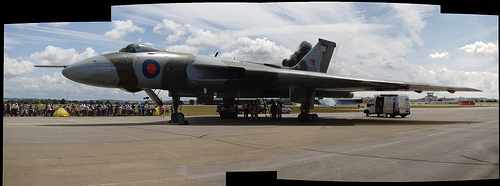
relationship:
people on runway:
[8, 97, 174, 117] [23, 121, 496, 166]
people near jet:
[8, 97, 174, 117] [46, 40, 477, 133]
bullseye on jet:
[137, 60, 163, 79] [46, 40, 477, 133]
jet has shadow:
[46, 40, 477, 133] [43, 119, 479, 131]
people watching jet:
[8, 97, 174, 117] [46, 40, 477, 133]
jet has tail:
[46, 40, 477, 133] [278, 34, 352, 91]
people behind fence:
[8, 97, 174, 117] [14, 116, 178, 119]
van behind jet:
[366, 93, 414, 118] [46, 40, 477, 133]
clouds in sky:
[144, 8, 282, 57] [142, 11, 485, 43]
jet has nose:
[46, 40, 477, 133] [64, 37, 104, 93]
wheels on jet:
[164, 114, 323, 132] [46, 40, 477, 133]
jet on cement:
[46, 40, 477, 133] [109, 126, 353, 169]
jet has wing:
[46, 40, 477, 133] [248, 37, 495, 109]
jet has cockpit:
[46, 40, 477, 133] [119, 45, 168, 68]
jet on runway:
[46, 40, 477, 133] [23, 121, 496, 166]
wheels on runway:
[164, 114, 323, 132] [23, 121, 496, 166]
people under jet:
[8, 97, 174, 117] [46, 40, 477, 133]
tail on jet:
[278, 34, 352, 91] [46, 40, 477, 133]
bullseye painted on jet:
[137, 60, 163, 79] [46, 40, 477, 133]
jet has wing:
[46, 40, 477, 133] [242, 67, 484, 93]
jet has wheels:
[46, 40, 477, 133] [164, 114, 323, 132]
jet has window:
[46, 40, 477, 133] [118, 35, 137, 60]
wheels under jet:
[164, 114, 323, 132] [46, 40, 477, 133]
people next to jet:
[8, 97, 174, 117] [46, 40, 477, 133]